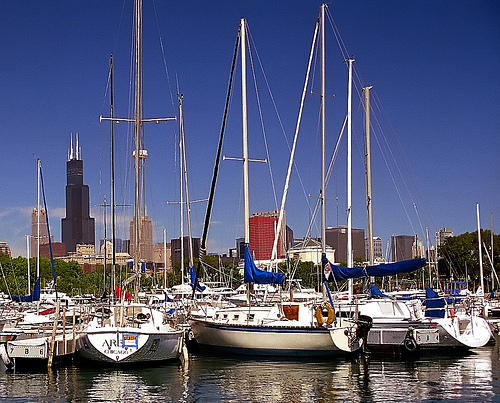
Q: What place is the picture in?
A: It is at the city.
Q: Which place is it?
A: It is a city.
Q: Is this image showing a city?
A: Yes, it is showing a city.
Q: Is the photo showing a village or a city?
A: It is showing a city.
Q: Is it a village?
A: No, it is a city.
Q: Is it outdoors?
A: Yes, it is outdoors.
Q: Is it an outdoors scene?
A: Yes, it is outdoors.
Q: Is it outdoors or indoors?
A: It is outdoors.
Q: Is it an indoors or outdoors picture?
A: It is outdoors.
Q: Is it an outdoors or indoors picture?
A: It is outdoors.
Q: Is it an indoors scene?
A: No, it is outdoors.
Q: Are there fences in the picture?
A: No, there are no fences.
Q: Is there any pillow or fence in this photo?
A: No, there are no fences or pillows.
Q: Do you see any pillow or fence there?
A: No, there are no fences or pillows.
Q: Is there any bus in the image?
A: No, there are no buses.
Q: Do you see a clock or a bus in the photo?
A: No, there are no buses or clocks.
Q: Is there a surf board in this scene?
A: No, there are no surfboards.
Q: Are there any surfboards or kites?
A: No, there are no surfboards or kites.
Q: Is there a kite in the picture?
A: No, there are no kites.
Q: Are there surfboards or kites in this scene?
A: No, there are no kites or surfboards.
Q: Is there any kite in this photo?
A: No, there are no kites.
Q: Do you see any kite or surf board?
A: No, there are no kites or surfboards.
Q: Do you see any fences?
A: No, there are no fences.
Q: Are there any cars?
A: No, there are no cars.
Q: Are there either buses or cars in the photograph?
A: No, there are no cars or buses.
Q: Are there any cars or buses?
A: No, there are no cars or buses.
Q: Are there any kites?
A: No, there are no kites.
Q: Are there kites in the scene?
A: No, there are no kites.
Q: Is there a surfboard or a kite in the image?
A: No, there are no kites or surfboards.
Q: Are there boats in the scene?
A: Yes, there is a boat.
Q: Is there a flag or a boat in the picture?
A: Yes, there is a boat.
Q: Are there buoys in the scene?
A: No, there are no buoys.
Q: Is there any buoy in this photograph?
A: No, there are no buoys.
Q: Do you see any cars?
A: No, there are no cars.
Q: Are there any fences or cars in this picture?
A: No, there are no cars or fences.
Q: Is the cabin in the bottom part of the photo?
A: Yes, the cabin is in the bottom of the image.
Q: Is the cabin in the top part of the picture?
A: No, the cabin is in the bottom of the image.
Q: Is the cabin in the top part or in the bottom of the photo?
A: The cabin is in the bottom of the image.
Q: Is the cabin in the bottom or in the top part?
A: The cabin is in the bottom of the image.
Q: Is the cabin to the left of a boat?
A: No, the cabin is to the right of a boat.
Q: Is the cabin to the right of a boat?
A: No, the cabin is to the left of a boat.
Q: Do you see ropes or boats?
A: Yes, there is a boat.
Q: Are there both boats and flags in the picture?
A: Yes, there are both a boat and a flag.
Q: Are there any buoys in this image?
A: No, there are no buoys.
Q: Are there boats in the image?
A: Yes, there is a boat.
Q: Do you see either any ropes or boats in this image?
A: Yes, there is a boat.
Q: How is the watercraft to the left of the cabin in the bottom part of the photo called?
A: The watercraft is a boat.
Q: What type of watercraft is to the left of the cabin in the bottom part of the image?
A: The watercraft is a boat.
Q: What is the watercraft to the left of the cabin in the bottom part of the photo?
A: The watercraft is a boat.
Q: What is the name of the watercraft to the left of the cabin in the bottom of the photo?
A: The watercraft is a boat.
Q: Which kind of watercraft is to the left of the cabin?
A: The watercraft is a boat.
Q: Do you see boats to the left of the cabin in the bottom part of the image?
A: Yes, there is a boat to the left of the cabin.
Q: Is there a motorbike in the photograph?
A: No, there are no motorcycles.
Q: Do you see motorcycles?
A: No, there are no motorcycles.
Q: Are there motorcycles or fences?
A: No, there are no motorcycles or fences.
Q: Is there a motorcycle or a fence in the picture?
A: No, there are no motorcycles or fences.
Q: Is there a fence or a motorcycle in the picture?
A: No, there are no motorcycles or fences.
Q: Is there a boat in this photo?
A: Yes, there is a boat.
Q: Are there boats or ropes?
A: Yes, there is a boat.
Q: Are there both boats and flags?
A: Yes, there are both a boat and a flag.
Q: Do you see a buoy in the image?
A: No, there are no buoys.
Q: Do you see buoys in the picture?
A: No, there are no buoys.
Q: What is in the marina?
A: The boat is in the marina.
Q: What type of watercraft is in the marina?
A: The watercraft is a boat.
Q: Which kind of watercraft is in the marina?
A: The watercraft is a boat.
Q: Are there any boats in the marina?
A: Yes, there is a boat in the marina.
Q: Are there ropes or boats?
A: Yes, there is a boat.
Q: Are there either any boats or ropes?
A: Yes, there is a boat.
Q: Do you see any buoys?
A: No, there are no buoys.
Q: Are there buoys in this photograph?
A: No, there are no buoys.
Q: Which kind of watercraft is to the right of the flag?
A: The watercraft is a boat.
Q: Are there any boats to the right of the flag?
A: Yes, there is a boat to the right of the flag.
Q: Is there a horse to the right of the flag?
A: No, there is a boat to the right of the flag.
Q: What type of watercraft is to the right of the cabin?
A: The watercraft is a boat.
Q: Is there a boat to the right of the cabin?
A: Yes, there is a boat to the right of the cabin.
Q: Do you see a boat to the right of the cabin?
A: Yes, there is a boat to the right of the cabin.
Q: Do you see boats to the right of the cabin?
A: Yes, there is a boat to the right of the cabin.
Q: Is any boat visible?
A: Yes, there is a boat.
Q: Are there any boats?
A: Yes, there is a boat.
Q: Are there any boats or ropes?
A: Yes, there is a boat.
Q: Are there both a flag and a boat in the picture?
A: Yes, there are both a boat and a flag.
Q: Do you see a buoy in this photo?
A: No, there are no buoys.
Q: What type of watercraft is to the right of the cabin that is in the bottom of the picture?
A: The watercraft is a boat.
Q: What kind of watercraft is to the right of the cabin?
A: The watercraft is a boat.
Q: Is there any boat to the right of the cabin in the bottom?
A: Yes, there is a boat to the right of the cabin.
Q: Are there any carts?
A: No, there are no carts.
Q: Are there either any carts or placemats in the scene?
A: No, there are no carts or placemats.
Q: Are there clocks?
A: No, there are no clocks.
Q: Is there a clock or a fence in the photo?
A: No, there are no clocks or fences.